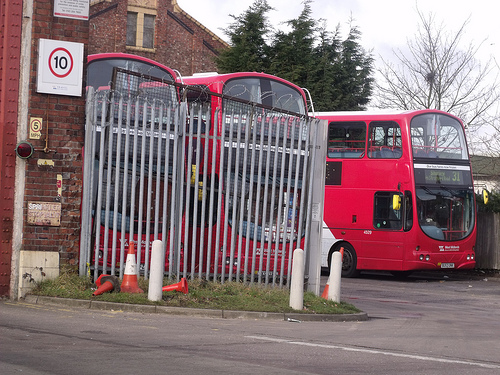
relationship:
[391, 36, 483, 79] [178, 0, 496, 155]
cloud cover in sky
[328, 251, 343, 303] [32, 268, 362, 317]
post in grass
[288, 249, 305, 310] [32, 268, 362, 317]
post in grass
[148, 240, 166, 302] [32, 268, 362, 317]
post in grass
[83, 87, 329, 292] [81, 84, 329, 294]
poles of fence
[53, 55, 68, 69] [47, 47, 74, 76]
10 in circle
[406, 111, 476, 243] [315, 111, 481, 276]
windows on front bus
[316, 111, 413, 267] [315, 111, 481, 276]
side of bus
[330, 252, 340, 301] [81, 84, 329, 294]
post near fence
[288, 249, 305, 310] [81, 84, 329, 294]
post near fence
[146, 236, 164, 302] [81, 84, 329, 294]
post near fence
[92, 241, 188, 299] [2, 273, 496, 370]
cones on ground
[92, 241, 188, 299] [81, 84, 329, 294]
cones near fence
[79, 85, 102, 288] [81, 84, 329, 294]
posts in fence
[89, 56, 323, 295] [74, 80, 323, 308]
buses behind fence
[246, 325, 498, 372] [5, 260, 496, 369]
lines in lot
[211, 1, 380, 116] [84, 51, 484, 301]
tree behind buses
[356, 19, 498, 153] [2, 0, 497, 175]
tree in distance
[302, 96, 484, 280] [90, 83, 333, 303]
bus not behind gate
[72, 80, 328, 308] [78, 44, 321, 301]
gates in front of buses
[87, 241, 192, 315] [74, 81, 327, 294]
cones in front of gate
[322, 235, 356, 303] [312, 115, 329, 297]
cone behind pole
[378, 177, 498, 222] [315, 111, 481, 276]
mirrors on bus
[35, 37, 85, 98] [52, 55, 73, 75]
sign with 10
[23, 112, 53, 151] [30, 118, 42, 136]
sign with 5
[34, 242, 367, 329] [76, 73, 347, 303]
median in front of gates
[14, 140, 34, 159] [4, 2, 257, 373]
light on left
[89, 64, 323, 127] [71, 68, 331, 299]
wire on top of fencing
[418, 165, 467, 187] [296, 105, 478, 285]
sign on bus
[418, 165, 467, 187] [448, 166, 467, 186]
sign indicates 31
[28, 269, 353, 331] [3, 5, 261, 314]
grass besides building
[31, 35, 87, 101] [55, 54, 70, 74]
sign with 10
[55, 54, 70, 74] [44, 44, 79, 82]
10 in circle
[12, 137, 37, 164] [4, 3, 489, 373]
light attached to building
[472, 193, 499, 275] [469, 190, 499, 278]
portion of fence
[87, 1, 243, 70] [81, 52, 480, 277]
building behind buses